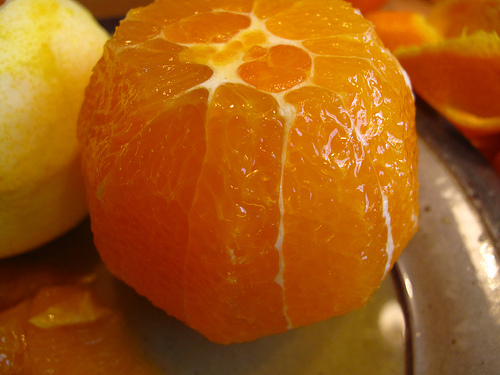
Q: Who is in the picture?
A: No one.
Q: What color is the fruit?
A: Orange.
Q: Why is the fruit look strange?
A: It is peeled.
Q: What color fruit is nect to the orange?
A: Yellow.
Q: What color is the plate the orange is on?
A: Silver.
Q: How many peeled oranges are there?
A: One.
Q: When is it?
A: Day time.